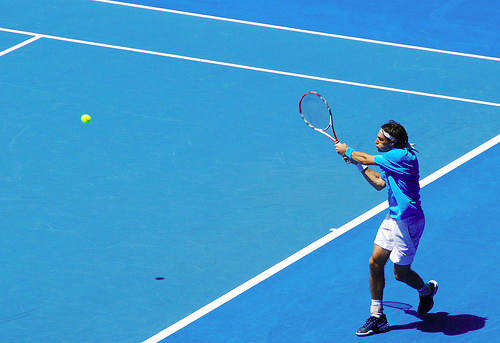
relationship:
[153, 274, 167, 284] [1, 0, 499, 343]
shadow on court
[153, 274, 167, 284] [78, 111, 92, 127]
shadow of tennis ball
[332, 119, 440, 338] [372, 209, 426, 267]
tennis player wearing shorts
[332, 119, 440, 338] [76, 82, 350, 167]
tennis player playing tennis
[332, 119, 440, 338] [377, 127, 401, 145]
tennis player wearing headband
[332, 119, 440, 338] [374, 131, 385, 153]
tennis player has face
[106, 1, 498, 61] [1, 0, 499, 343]
line on court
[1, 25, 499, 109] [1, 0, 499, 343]
line on court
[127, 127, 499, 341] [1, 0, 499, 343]
line on court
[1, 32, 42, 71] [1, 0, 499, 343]
line on court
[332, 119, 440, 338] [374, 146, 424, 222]
tennis player wearing shirt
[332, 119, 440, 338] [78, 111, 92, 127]
tennis player hitting tennis ball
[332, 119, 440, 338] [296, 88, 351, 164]
tennis player holding tennis racket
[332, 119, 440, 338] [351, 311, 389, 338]
tennis player wearing shoe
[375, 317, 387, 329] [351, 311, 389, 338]
nike emblem on shoe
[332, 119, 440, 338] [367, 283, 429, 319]
tennis player wearing socks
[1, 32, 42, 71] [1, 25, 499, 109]
line connected to line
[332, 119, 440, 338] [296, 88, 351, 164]
tennis player swinging tennis racket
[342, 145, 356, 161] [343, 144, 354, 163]
sweat band on wrist